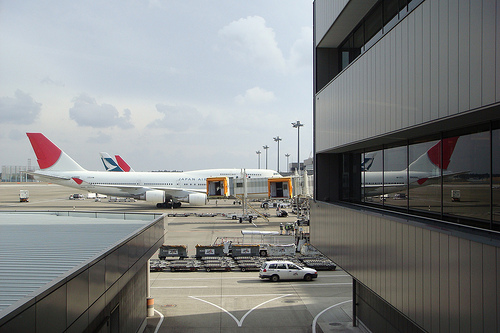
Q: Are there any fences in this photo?
A: No, there are no fences.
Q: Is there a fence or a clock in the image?
A: No, there are no fences or clocks.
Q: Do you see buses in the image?
A: No, there are no buses.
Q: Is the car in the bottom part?
A: Yes, the car is in the bottom of the image.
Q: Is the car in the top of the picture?
A: No, the car is in the bottom of the image.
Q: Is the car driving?
A: Yes, the car is driving.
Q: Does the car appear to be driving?
A: Yes, the car is driving.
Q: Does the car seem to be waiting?
A: No, the car is driving.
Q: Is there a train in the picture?
A: No, there are no trains.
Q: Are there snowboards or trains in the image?
A: No, there are no trains or snowboards.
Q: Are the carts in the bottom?
A: Yes, the carts are in the bottom of the image.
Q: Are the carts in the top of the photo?
A: No, the carts are in the bottom of the image.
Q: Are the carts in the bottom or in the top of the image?
A: The carts are in the bottom of the image.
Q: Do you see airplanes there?
A: Yes, there is an airplane.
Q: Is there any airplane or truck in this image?
A: Yes, there is an airplane.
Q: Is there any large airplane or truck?
A: Yes, there is a large airplane.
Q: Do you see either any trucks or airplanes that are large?
A: Yes, the airplane is large.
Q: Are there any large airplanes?
A: Yes, there is a large airplane.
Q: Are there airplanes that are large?
A: Yes, there is an airplane that is large.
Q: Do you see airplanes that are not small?
A: Yes, there is a large airplane.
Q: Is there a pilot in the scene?
A: No, there are no pilots.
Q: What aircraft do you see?
A: The aircraft is an airplane.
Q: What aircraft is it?
A: The aircraft is an airplane.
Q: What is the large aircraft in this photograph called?
A: The aircraft is an airplane.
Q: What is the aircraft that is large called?
A: The aircraft is an airplane.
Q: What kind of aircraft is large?
A: The aircraft is an airplane.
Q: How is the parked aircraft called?
A: The aircraft is an airplane.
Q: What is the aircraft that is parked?
A: The aircraft is an airplane.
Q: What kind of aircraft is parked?
A: The aircraft is an airplane.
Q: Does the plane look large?
A: Yes, the plane is large.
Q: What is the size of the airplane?
A: The airplane is large.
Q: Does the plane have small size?
A: No, the plane is large.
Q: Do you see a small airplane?
A: No, there is an airplane but it is large.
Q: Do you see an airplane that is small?
A: No, there is an airplane but it is large.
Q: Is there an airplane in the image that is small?
A: No, there is an airplane but it is large.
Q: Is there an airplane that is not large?
A: No, there is an airplane but it is large.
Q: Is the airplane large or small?
A: The airplane is large.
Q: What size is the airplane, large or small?
A: The airplane is large.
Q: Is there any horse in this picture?
A: No, there are no horses.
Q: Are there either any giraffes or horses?
A: No, there are no horses or giraffes.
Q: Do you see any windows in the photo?
A: Yes, there is a window.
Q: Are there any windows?
A: Yes, there is a window.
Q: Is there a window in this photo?
A: Yes, there is a window.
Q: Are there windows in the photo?
A: Yes, there is a window.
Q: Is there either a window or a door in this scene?
A: Yes, there is a window.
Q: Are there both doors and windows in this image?
A: No, there is a window but no doors.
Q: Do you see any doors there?
A: No, there are no doors.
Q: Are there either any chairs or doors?
A: No, there are no doors or chairs.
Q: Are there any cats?
A: No, there are no cats.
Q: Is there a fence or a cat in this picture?
A: No, there are no cats or fences.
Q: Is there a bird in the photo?
A: No, there are no birds.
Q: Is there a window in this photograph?
A: Yes, there are windows.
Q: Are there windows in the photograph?
A: Yes, there are windows.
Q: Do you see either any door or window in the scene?
A: Yes, there are windows.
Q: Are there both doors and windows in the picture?
A: No, there are windows but no doors.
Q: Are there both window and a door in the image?
A: No, there are windows but no doors.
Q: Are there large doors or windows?
A: Yes, there are large windows.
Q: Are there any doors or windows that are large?
A: Yes, the windows are large.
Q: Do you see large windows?
A: Yes, there are large windows.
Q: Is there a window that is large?
A: Yes, there are windows that are large.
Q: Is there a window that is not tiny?
A: Yes, there are large windows.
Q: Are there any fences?
A: No, there are no fences.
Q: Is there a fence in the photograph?
A: No, there are no fences.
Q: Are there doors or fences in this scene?
A: No, there are no fences or doors.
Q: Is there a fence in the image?
A: No, there are no fences.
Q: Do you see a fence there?
A: No, there are no fences.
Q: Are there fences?
A: No, there are no fences.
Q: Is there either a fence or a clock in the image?
A: No, there are no fences or clocks.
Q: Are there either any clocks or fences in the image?
A: No, there are no fences or clocks.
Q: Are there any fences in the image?
A: No, there are no fences.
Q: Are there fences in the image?
A: No, there are no fences.